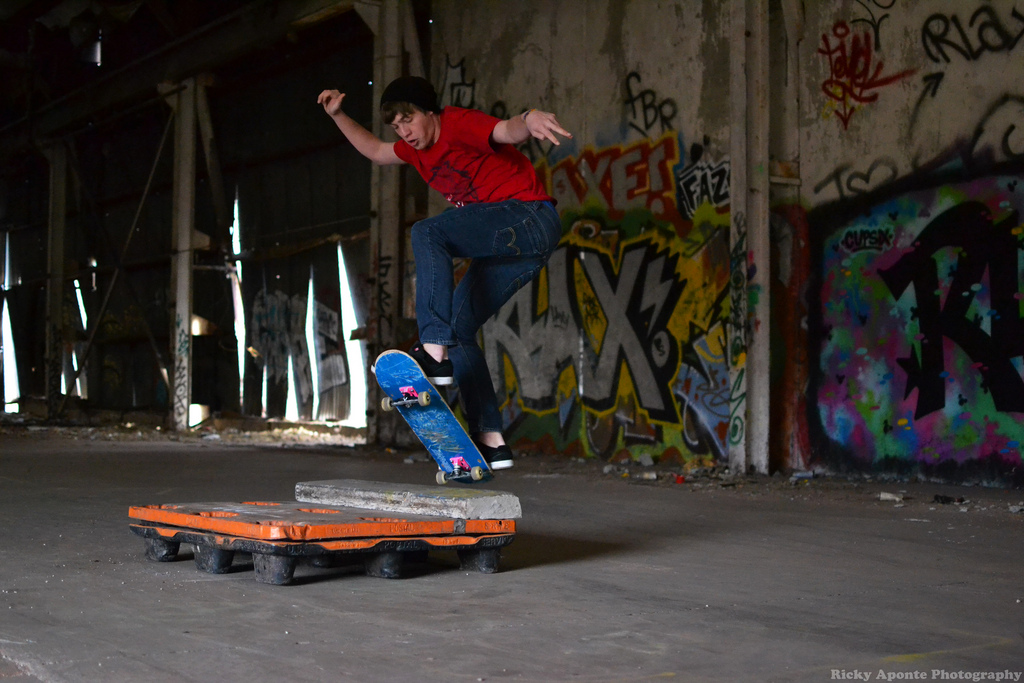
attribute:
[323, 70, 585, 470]
man — one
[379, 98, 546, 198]
shirt — red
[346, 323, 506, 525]
skateboard — blue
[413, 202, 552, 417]
jeans — blue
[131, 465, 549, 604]
pallet — orange, black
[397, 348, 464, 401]
shoe — black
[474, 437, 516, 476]
shoe — black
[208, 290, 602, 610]
skateboard — used, blue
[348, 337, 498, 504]
skateboard — blue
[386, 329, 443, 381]
sneakers — black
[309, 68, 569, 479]
boy — young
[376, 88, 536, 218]
shirt — red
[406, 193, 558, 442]
jeans — blue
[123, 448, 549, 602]
platform — orange, white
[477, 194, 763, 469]
graphiti — colorful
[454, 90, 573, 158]
man's arm — young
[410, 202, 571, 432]
jeans — blue